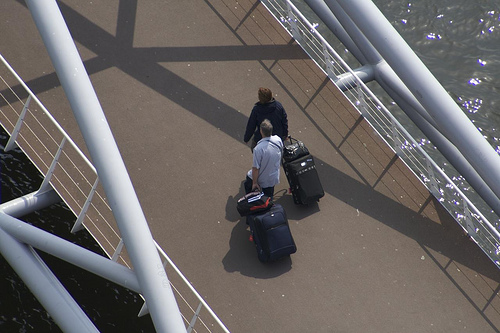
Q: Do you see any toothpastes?
A: No, there are no toothpastes.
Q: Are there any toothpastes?
A: No, there are no toothpastes.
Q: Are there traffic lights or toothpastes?
A: No, there are no toothpastes or traffic lights.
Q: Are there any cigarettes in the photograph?
A: No, there are no cigarettes.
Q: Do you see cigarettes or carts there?
A: No, there are no cigarettes or carts.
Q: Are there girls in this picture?
A: No, there are no girls.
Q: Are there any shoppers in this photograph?
A: No, there are no shoppers.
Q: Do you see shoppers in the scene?
A: No, there are no shoppers.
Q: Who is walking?
A: The man is walking.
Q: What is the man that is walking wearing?
A: The man is wearing a shirt.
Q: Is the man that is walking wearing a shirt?
A: Yes, the man is wearing a shirt.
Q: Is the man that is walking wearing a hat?
A: No, the man is wearing a shirt.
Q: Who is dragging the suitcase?
A: The man is dragging the suitcase.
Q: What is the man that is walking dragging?
A: The man is dragging the suitcase.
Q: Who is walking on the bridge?
A: The man is walking on the bridge.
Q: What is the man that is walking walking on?
A: The man is walking on the bridge.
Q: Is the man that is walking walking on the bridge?
A: Yes, the man is walking on the bridge.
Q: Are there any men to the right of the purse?
A: No, the man is to the left of the purse.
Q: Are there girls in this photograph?
A: No, there are no girls.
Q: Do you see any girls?
A: No, there are no girls.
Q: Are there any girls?
A: No, there are no girls.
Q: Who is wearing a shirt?
A: The man is wearing a shirt.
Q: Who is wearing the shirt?
A: The man is wearing a shirt.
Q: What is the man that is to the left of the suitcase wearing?
A: The man is wearing a shirt.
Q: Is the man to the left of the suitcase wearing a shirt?
A: Yes, the man is wearing a shirt.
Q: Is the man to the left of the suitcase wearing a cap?
A: No, the man is wearing a shirt.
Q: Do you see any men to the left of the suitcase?
A: Yes, there is a man to the left of the suitcase.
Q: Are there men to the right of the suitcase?
A: No, the man is to the left of the suitcase.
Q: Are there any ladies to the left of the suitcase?
A: No, there is a man to the left of the suitcase.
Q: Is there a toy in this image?
A: No, there are no toys.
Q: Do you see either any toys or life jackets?
A: No, there are no toys or life jackets.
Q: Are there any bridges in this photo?
A: Yes, there is a bridge.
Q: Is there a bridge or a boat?
A: Yes, there is a bridge.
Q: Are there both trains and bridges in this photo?
A: No, there is a bridge but no trains.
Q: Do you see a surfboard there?
A: No, there are no surfboards.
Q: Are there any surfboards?
A: No, there are no surfboards.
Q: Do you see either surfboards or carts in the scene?
A: No, there are no surfboards or carts.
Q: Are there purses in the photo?
A: Yes, there is a purse.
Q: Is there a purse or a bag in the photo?
A: Yes, there is a purse.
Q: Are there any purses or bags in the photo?
A: Yes, there is a purse.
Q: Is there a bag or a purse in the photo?
A: Yes, there is a purse.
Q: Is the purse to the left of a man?
A: No, the purse is to the right of a man.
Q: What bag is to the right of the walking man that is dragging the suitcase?
A: The bag is a purse.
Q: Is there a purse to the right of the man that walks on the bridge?
A: Yes, there is a purse to the right of the man.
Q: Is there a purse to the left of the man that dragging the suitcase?
A: No, the purse is to the right of the man.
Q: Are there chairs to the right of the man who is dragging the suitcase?
A: No, there is a purse to the right of the man.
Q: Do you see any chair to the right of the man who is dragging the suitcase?
A: No, there is a purse to the right of the man.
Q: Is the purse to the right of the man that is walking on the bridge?
A: Yes, the purse is to the right of the man.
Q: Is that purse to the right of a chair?
A: No, the purse is to the right of the man.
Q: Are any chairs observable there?
A: No, there are no chairs.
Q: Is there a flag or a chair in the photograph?
A: No, there are no chairs or flags.